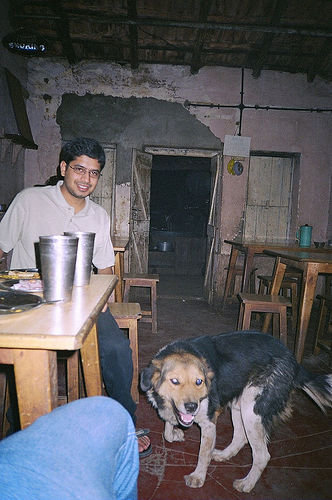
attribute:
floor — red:
[130, 388, 330, 498]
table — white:
[4, 278, 127, 416]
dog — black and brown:
[138, 328, 330, 493]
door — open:
[129, 148, 153, 298]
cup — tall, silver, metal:
[62, 224, 103, 295]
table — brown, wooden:
[273, 249, 319, 290]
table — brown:
[264, 245, 331, 364]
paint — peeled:
[49, 79, 241, 150]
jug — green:
[298, 224, 312, 247]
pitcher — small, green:
[292, 220, 311, 247]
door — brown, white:
[128, 147, 151, 304]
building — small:
[0, 0, 331, 305]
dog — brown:
[178, 321, 244, 429]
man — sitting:
[42, 144, 110, 279]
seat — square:
[237, 290, 294, 307]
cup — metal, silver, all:
[37, 235, 79, 303]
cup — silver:
[62, 230, 95, 287]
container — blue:
[296, 220, 312, 248]